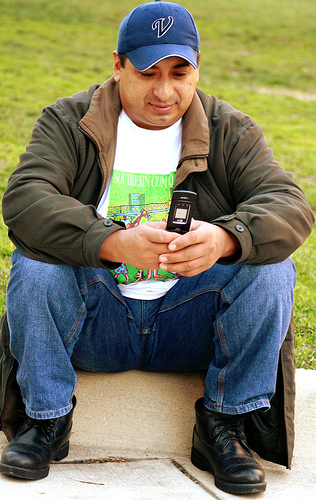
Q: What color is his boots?
A: Black.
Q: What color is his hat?
A: Blue.